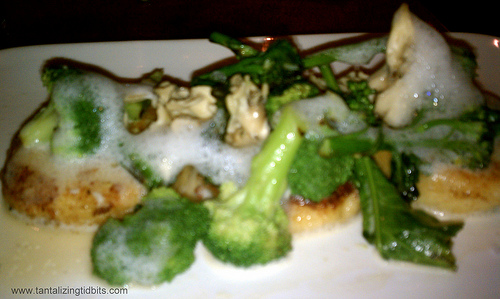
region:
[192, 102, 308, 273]
a piece of green broccoli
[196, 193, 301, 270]
the head of the broccoli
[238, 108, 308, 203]
the stem of the broccoli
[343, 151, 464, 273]
a green leaf of spinach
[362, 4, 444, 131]
a piece of brown mushroom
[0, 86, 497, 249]
a piece of chicken on the plate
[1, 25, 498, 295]
a white porcelain plate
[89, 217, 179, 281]
white dressing on the broccoli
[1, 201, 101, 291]
brown sauce on the plate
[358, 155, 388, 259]
a vein in the spinach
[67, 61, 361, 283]
the food is blurred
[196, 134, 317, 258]
the food is blurred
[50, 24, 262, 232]
the food is blurred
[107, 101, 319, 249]
the food is blurred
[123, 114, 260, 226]
the food is blurred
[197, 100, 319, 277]
a piece of broccoli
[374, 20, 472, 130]
white foaming substance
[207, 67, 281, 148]
a tan vegetable on the plate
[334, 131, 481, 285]
a cooked leaf on the plate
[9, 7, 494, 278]
a pile of green vegetables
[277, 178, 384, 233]
cooked brown meat underneath the broccoli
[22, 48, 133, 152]
white foam on a piece of vegetable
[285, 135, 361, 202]
the green top of broccoli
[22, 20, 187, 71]
piece of white plate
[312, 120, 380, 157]
stem of the broccoli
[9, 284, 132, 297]
web address for photographer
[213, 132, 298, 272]
cooked piece of green broccoli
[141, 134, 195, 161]
white foam on cooked food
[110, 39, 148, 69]
white dining plate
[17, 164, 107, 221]
side of cooked brown scallop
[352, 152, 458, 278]
cooked green broccoli leaf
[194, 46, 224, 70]
food reflecting from camera flash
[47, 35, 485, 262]
cooked food on white serving plate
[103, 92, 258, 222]
food covered in white foam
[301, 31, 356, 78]
cooked green broccoli stem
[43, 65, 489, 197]
broccoli with soap bubbles on it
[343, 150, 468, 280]
Shiny Green leafy item on plate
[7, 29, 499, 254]
a white plate with green vegetables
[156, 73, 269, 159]
White chunks among the green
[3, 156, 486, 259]
a yellow sauce on the bottom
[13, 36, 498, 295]
a white plate of food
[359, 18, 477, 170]
white bubbles on a white chunk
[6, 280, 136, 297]
Website address in black lettters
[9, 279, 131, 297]
website address in lower left corner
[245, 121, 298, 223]
reflection of light on broccoli stem